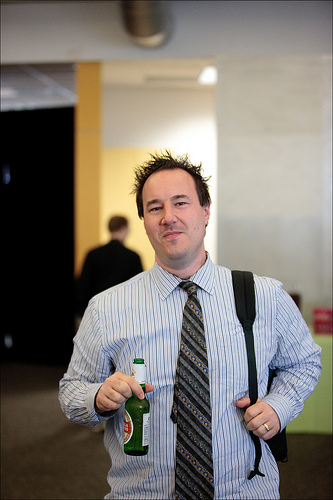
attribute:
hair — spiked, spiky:
[125, 146, 212, 222]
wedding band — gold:
[260, 421, 274, 433]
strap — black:
[227, 263, 270, 486]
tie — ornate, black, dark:
[169, 277, 220, 500]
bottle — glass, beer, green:
[122, 355, 154, 463]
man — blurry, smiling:
[71, 211, 147, 328]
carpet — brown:
[3, 365, 332, 500]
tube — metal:
[117, 2, 177, 53]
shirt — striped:
[55, 253, 325, 500]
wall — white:
[2, 2, 332, 325]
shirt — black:
[77, 236, 146, 320]